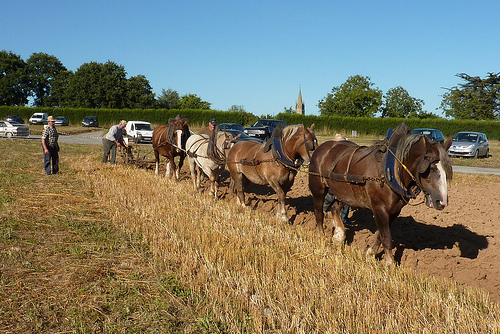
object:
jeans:
[42, 145, 59, 175]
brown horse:
[226, 122, 320, 225]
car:
[54, 116, 69, 126]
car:
[29, 112, 48, 125]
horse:
[309, 132, 454, 266]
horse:
[185, 132, 242, 199]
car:
[124, 120, 154, 143]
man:
[101, 119, 127, 164]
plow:
[120, 144, 156, 169]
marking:
[435, 161, 448, 206]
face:
[420, 149, 449, 209]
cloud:
[0, 0, 498, 107]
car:
[447, 131, 490, 158]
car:
[411, 128, 445, 143]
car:
[81, 116, 99, 127]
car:
[0, 118, 31, 139]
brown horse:
[152, 118, 191, 180]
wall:
[266, 129, 269, 137]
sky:
[0, 0, 499, 70]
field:
[0, 130, 500, 334]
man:
[40, 116, 62, 176]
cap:
[46, 116, 56, 122]